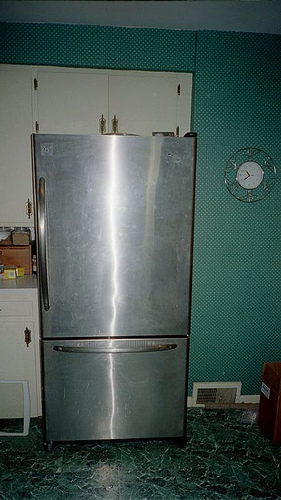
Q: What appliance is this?
A: A refrigerator.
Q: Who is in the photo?
A: Nobody.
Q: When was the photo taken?
A: 10:40.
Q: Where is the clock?
A: On the wall.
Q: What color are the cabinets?
A: White.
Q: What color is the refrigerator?
A: Silver.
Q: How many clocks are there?
A: One.